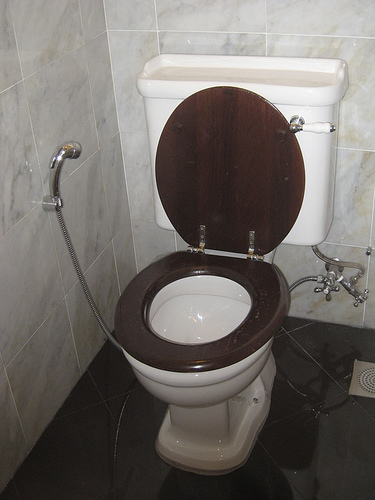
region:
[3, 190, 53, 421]
White marble wall tile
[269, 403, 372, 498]
Black ceramic floor tile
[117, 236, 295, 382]
Wooden toilet seat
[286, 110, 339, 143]
White handle on toilet tank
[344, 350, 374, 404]
Beige bathroom floor drain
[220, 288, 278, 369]
Scratches on wooden toilet seat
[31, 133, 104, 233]
Silver spray nozzle in holder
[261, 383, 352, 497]
Reflection of toilet in floor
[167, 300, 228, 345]
Clean white toilet bowl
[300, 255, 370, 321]
Silver water line cut-off knobs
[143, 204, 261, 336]
the toilet seat is brown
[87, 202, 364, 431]
the toilet seat is brown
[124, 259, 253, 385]
the toilet seat is brown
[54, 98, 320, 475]
the toilet seat is brown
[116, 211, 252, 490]
the toilet seat is brown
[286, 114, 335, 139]
White and silver flusher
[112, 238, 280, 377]
Dark brown toilet seat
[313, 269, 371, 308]
Silver knob on pipes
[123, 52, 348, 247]
White toilet tank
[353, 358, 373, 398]
Silver drain duct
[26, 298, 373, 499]
Dark brown tiled floor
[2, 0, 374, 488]
Marble beige walls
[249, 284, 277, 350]
Spots on brown toilet seat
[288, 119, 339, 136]
White handle with silver tip and base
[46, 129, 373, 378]
Silver pipe behind toilet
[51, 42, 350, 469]
A white toilet with brown seat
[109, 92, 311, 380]
A wooden looking toilet seat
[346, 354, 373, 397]
White drain in floor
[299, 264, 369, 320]
Silver knobs for water control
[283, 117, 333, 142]
White and silver handle of toilet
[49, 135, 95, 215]
Water sprayer hooked to wall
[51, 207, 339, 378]
Hose travels behind the toilet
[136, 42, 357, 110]
A white lid on back of toilet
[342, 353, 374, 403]
White square around drain in floor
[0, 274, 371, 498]
A dark brown floor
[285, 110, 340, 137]
white toilet handle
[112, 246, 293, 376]
dark brown toilet seat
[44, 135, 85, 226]
shiny chrome shower head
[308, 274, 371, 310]
two water faucet handles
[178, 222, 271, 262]
two metal toilet hinges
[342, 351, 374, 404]
shiny metal bathroom floor drain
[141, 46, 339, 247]
white toilet tank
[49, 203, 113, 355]
ridged metal shower hose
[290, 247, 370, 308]
shiny metal bathroom water hoses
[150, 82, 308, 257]
dark brown toilet lid